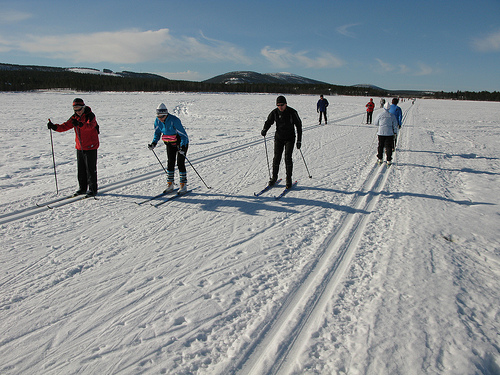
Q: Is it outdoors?
A: Yes, it is outdoors.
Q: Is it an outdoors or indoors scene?
A: It is outdoors.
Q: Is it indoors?
A: No, it is outdoors.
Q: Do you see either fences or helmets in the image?
A: No, there are no fences or helmets.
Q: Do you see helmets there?
A: No, there are no helmets.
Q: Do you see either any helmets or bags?
A: No, there are no helmets or bags.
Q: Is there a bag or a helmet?
A: No, there are no helmets or bags.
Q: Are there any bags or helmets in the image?
A: No, there are no helmets or bags.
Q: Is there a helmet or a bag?
A: No, there are no helmets or bags.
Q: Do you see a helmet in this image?
A: No, there are no helmets.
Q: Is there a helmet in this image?
A: No, there are no helmets.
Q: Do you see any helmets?
A: No, there are no helmets.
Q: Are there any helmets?
A: No, there are no helmets.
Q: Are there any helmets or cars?
A: No, there are no helmets or cars.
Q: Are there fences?
A: No, there are no fences.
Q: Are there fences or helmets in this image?
A: No, there are no fences or helmets.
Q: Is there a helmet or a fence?
A: No, there are no fences or helmets.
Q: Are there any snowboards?
A: No, there are no snowboards.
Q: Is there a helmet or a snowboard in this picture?
A: No, there are no snowboards or helmets.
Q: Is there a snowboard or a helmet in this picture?
A: No, there are no snowboards or helmets.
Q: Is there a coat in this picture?
A: Yes, there is a coat.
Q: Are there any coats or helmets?
A: Yes, there is a coat.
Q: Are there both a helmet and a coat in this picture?
A: No, there is a coat but no helmets.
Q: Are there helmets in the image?
A: No, there are no helmets.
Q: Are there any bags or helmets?
A: No, there are no helmets or bags.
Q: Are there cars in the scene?
A: No, there are no cars.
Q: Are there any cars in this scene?
A: No, there are no cars.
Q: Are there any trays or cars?
A: No, there are no cars or trays.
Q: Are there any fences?
A: No, there are no fences.